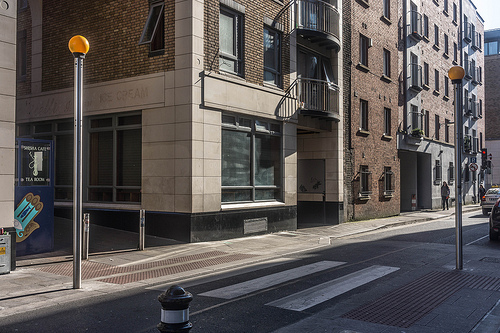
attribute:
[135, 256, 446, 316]
crosswalk — pedestrian, white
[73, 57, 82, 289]
pole — large, tall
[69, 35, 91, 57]
ball — yellow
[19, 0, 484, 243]
apartment — brick, muilti-storied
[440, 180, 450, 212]
woman — walking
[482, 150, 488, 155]
traffic-signal — red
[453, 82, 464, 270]
post — metal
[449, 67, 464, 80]
ball — yellow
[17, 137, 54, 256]
door — blue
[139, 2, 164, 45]
window — open, ajar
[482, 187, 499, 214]
car — stopped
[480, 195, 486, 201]
brake light — on